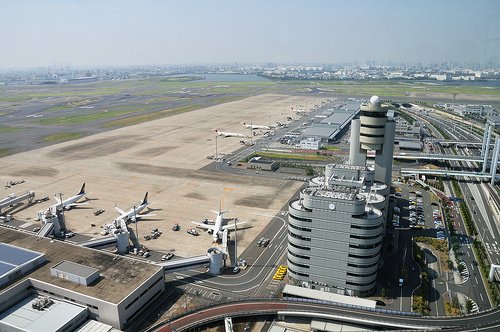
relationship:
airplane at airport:
[100, 191, 158, 229] [0, 84, 497, 330]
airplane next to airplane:
[192, 200, 247, 241] [100, 191, 158, 229]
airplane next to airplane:
[100, 191, 158, 229] [44, 181, 89, 211]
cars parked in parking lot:
[394, 189, 446, 235] [389, 181, 444, 236]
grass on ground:
[144, 81, 187, 99] [4, 84, 498, 182]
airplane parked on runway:
[100, 191, 158, 229] [3, 92, 333, 266]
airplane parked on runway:
[192, 200, 247, 241] [54, 145, 201, 176]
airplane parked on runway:
[100, 191, 158, 229] [54, 145, 201, 176]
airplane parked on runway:
[44, 181, 89, 211] [54, 145, 201, 176]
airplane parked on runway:
[211, 127, 252, 139] [3, 92, 333, 266]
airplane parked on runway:
[240, 117, 275, 130] [145, 115, 238, 181]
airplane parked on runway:
[211, 127, 252, 139] [145, 115, 238, 181]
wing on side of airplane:
[187, 212, 212, 233] [190, 199, 245, 240]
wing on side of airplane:
[133, 209, 156, 216] [44, 181, 89, 211]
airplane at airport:
[192, 200, 247, 241] [0, 77, 337, 267]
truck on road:
[394, 275, 407, 287] [392, 167, 416, 315]